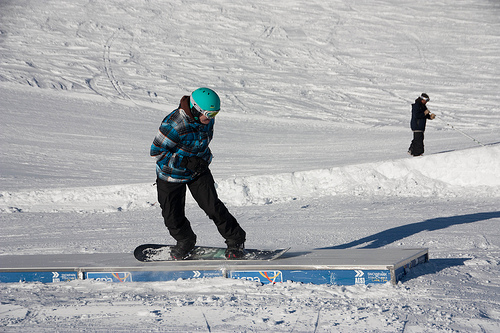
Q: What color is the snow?
A: White.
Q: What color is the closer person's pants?
A: Black.